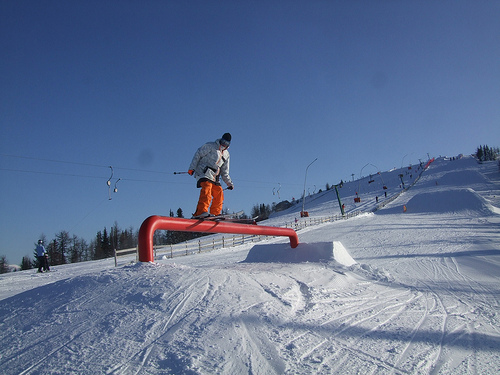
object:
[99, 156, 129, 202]
ski lift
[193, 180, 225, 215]
pants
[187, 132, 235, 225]
man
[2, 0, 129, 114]
sky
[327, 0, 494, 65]
sky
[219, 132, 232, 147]
head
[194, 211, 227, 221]
ski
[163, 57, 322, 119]
sky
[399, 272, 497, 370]
snow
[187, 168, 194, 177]
hand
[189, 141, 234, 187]
coat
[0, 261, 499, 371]
slope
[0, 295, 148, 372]
tracks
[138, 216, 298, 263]
pipe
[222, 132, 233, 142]
hat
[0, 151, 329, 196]
wires